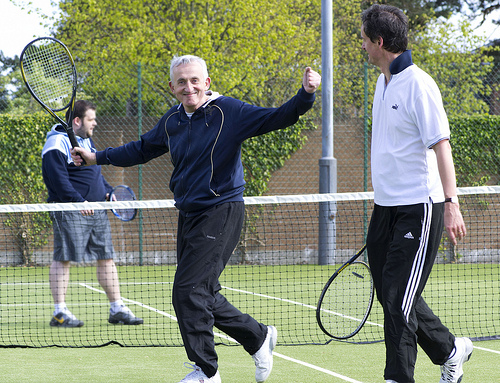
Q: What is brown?
A: Wall.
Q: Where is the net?
A: Middle of the court.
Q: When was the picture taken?
A: Daytime.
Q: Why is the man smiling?
A: He won.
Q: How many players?
A: Three.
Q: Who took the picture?
A: Man.